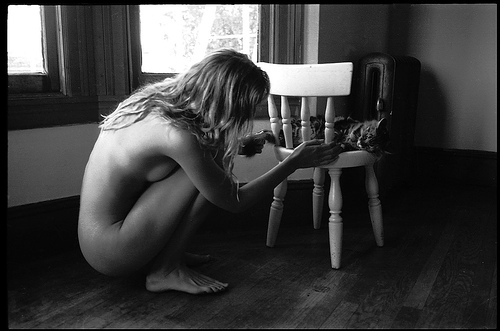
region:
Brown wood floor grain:
[334, 289, 371, 322]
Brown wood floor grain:
[375, 242, 420, 329]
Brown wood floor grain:
[433, 246, 468, 329]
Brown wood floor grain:
[266, 288, 366, 320]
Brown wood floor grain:
[129, 296, 199, 326]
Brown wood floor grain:
[27, 299, 99, 326]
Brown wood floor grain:
[30, 227, 84, 293]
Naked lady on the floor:
[64, 21, 394, 301]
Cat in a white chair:
[262, 106, 447, 246]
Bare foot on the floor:
[136, 264, 288, 303]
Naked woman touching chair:
[75, 48, 397, 295]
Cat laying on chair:
[261, 60, 398, 268]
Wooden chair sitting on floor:
[264, 58, 386, 268]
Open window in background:
[99, 25, 306, 107]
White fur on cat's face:
[354, 134, 366, 149]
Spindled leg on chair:
[327, 168, 344, 270]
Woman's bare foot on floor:
[145, 265, 229, 297]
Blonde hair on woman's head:
[99, 48, 271, 203]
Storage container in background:
[356, 52, 423, 194]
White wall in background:
[7, 122, 104, 207]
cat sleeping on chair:
[250, 112, 396, 154]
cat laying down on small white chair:
[242, 115, 389, 160]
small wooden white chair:
[254, 62, 390, 267]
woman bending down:
[82, 51, 339, 296]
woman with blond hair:
[78, 48, 343, 296]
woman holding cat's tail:
[73, 50, 343, 292]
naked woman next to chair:
[73, 46, 338, 294]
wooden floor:
[8, 166, 496, 328]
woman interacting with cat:
[84, 49, 341, 297]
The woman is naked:
[88, 94, 322, 329]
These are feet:
[108, 231, 226, 330]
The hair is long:
[120, 26, 252, 155]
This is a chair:
[254, 41, 446, 278]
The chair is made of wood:
[282, 62, 386, 262]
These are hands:
[241, 135, 348, 229]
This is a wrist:
[276, 161, 316, 203]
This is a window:
[11, 33, 95, 130]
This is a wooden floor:
[276, 249, 359, 304]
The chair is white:
[291, 229, 362, 299]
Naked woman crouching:
[75, 47, 341, 295]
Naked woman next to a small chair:
[72, 47, 387, 296]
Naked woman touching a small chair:
[77, 46, 388, 296]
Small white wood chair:
[252, 59, 384, 271]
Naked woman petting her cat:
[75, 47, 397, 295]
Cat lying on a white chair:
[242, 58, 390, 270]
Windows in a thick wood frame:
[6, 1, 298, 128]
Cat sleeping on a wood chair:
[244, 59, 391, 267]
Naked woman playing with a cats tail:
[75, 49, 395, 297]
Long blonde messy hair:
[95, 46, 270, 203]